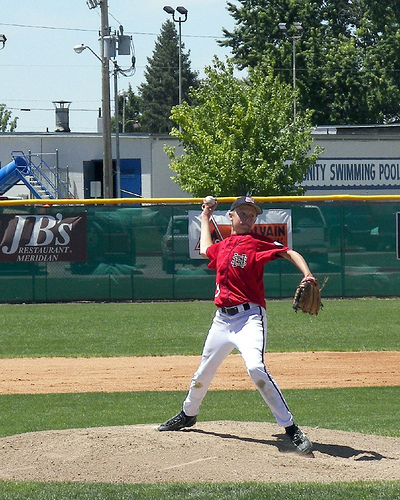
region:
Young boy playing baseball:
[150, 171, 324, 467]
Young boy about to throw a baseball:
[153, 170, 341, 473]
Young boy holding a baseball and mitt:
[150, 177, 338, 470]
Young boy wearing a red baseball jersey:
[146, 173, 335, 475]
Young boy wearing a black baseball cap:
[152, 183, 336, 463]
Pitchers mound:
[4, 361, 397, 491]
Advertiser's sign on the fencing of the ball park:
[2, 201, 96, 275]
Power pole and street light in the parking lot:
[68, 2, 146, 211]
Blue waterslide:
[0, 137, 72, 205]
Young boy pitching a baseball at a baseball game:
[3, 142, 399, 493]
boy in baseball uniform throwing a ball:
[156, 192, 323, 453]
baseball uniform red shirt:
[205, 232, 290, 310]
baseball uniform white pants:
[181, 295, 294, 427]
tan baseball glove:
[289, 274, 323, 316]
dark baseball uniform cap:
[229, 193, 263, 214]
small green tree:
[164, 53, 326, 198]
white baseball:
[204, 194, 214, 204]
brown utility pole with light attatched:
[72, 0, 137, 205]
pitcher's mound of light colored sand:
[0, 420, 397, 481]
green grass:
[0, 295, 398, 359]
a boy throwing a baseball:
[169, 155, 322, 495]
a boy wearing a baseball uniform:
[149, 158, 336, 452]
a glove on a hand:
[260, 255, 346, 329]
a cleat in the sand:
[235, 383, 346, 470]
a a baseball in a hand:
[169, 154, 229, 242]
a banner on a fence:
[7, 185, 114, 275]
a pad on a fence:
[10, 183, 399, 250]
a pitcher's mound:
[13, 378, 379, 499]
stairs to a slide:
[8, 125, 100, 242]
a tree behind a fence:
[160, 36, 337, 240]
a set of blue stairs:
[19, 151, 45, 209]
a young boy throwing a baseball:
[157, 185, 310, 424]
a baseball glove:
[288, 277, 329, 315]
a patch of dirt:
[0, 356, 147, 392]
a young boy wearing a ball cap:
[215, 189, 275, 238]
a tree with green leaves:
[178, 53, 300, 207]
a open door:
[70, 157, 113, 202]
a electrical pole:
[87, 14, 129, 191]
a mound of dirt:
[0, 410, 393, 491]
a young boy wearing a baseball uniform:
[177, 187, 287, 443]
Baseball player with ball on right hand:
[145, 174, 342, 466]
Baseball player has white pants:
[143, 181, 343, 461]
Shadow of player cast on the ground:
[210, 422, 391, 465]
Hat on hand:
[281, 271, 330, 323]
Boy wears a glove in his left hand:
[152, 183, 348, 470]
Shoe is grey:
[153, 410, 329, 454]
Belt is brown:
[207, 295, 254, 321]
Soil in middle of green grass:
[11, 412, 397, 498]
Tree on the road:
[159, 102, 319, 195]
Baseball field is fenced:
[1, 192, 202, 301]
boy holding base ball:
[168, 172, 256, 278]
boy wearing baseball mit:
[269, 260, 346, 332]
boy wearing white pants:
[128, 299, 338, 464]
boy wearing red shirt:
[185, 212, 306, 311]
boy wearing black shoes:
[152, 389, 205, 457]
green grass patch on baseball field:
[4, 296, 399, 358]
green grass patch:
[4, 391, 396, 439]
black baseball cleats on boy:
[147, 409, 317, 452]